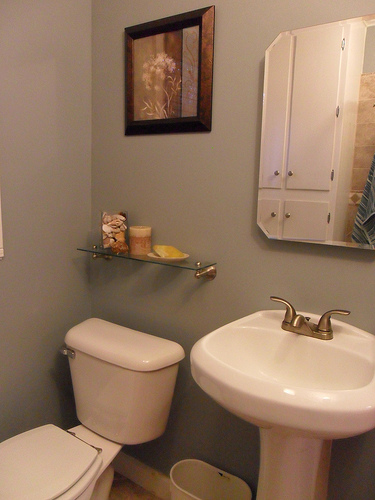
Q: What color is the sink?
A: White.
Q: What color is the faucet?
A: Gold.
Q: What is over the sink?
A: The mirror.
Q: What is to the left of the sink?
A: The toilet.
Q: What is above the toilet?
A: A shelf.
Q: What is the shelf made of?
A: Glass.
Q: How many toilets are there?
A: One.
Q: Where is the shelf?
A: Above the toilet.